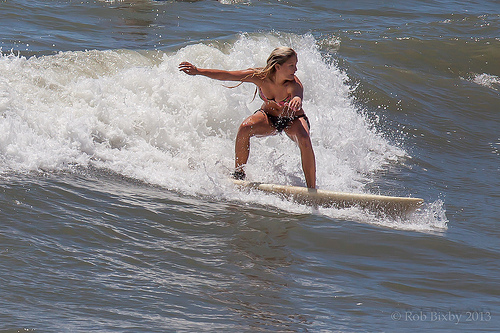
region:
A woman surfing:
[105, 31, 385, 198]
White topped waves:
[11, 51, 163, 166]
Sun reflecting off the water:
[66, 166, 236, 296]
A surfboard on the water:
[220, 160, 430, 225]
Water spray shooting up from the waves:
[140, 5, 185, 70]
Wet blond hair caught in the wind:
[220, 35, 300, 90]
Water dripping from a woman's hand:
[270, 90, 310, 131]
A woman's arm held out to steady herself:
[165, 50, 277, 90]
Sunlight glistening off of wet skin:
[227, 110, 252, 161]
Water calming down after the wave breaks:
[23, 159, 260, 295]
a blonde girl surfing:
[150, 30, 455, 231]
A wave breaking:
[240, 25, 475, 165]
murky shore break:
[75, 221, 305, 321]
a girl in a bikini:
[16, 18, 449, 233]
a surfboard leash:
[227, 160, 264, 192]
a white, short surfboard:
[222, 160, 417, 225]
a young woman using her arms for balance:
[165, 24, 442, 269]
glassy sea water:
[16, 5, 188, 41]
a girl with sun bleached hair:
[240, 32, 320, 99]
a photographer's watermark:
[386, 297, 463, 331]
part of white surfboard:
[322, 187, 431, 209]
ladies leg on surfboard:
[289, 129, 324, 189]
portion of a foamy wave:
[4, 62, 146, 128]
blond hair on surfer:
[272, 44, 294, 62]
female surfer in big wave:
[170, 37, 334, 205]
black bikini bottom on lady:
[260, 110, 301, 130]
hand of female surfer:
[177, 60, 197, 78]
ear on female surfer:
[273, 62, 281, 71]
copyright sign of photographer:
[379, 304, 499, 331]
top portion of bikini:
[252, 89, 287, 107]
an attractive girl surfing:
[195, 48, 359, 192]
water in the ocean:
[65, 213, 280, 330]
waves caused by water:
[60, 56, 180, 163]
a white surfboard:
[243, 178, 447, 210]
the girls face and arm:
[168, 48, 312, 78]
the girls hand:
[292, 96, 313, 113]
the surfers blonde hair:
[243, 40, 293, 82]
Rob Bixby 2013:
[385, 307, 498, 327]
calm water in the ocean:
[415, 6, 492, 155]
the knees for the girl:
[231, 126, 324, 190]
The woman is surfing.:
[158, 36, 453, 256]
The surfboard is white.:
[225, 165, 425, 230]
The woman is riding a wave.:
[1, 10, 492, 245]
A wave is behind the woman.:
[0, 31, 486, 187]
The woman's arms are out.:
[175, 45, 325, 165]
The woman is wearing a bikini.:
[230, 40, 322, 205]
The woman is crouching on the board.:
[165, 35, 335, 206]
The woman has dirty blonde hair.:
[235, 45, 312, 120]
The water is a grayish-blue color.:
[60, 185, 240, 326]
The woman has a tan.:
[176, 27, 333, 222]